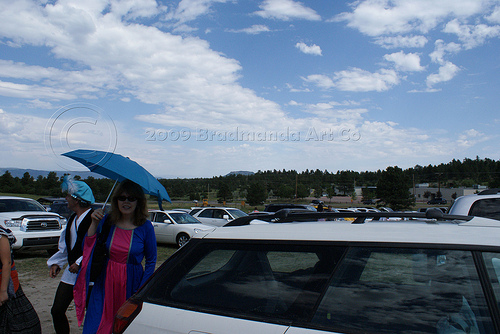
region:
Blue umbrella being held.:
[58, 144, 168, 236]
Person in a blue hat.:
[46, 176, 101, 332]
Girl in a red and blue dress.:
[77, 180, 163, 332]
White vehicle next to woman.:
[119, 218, 499, 330]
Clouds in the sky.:
[2, 1, 487, 177]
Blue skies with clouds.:
[2, 3, 497, 180]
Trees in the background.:
[5, 155, 495, 201]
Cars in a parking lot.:
[5, 191, 499, 255]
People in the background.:
[190, 186, 450, 216]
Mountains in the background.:
[2, 161, 252, 184]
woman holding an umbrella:
[47, 116, 167, 315]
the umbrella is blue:
[70, 122, 190, 218]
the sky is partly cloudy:
[78, 10, 410, 160]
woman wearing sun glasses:
[95, 182, 146, 212]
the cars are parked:
[165, 180, 467, 276]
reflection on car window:
[296, 255, 477, 325]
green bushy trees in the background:
[247, 135, 494, 210]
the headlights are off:
[10, 210, 80, 232]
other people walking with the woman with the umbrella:
[0, 175, 160, 315]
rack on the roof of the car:
[230, 191, 475, 228]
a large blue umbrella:
[62, 143, 173, 221]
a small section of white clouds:
[297, 65, 400, 96]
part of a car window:
[161, 246, 328, 316]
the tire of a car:
[172, 232, 189, 247]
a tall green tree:
[21, 167, 36, 186]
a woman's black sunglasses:
[113, 193, 138, 203]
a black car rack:
[224, 207, 470, 225]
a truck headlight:
[7, 219, 24, 227]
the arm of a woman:
[142, 226, 157, 290]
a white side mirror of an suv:
[221, 214, 229, 220]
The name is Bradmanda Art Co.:
[202, 125, 365, 146]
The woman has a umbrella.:
[74, 129, 178, 245]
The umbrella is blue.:
[65, 135, 177, 210]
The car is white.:
[163, 190, 458, 327]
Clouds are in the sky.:
[41, 5, 423, 121]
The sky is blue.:
[244, 45, 285, 70]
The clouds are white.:
[106, 28, 221, 85]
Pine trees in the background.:
[190, 164, 386, 196]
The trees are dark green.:
[246, 172, 293, 191]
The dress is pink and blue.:
[95, 219, 157, 301]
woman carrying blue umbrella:
[78, 135, 172, 220]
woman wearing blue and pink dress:
[91, 225, 184, 304]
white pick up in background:
[2, 198, 57, 252]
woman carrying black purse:
[100, 228, 124, 275]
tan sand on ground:
[33, 264, 54, 302]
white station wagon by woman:
[201, 212, 353, 289]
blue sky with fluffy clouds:
[227, 82, 324, 123]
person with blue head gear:
[51, 169, 95, 211]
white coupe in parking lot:
[164, 212, 215, 239]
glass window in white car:
[176, 253, 239, 300]